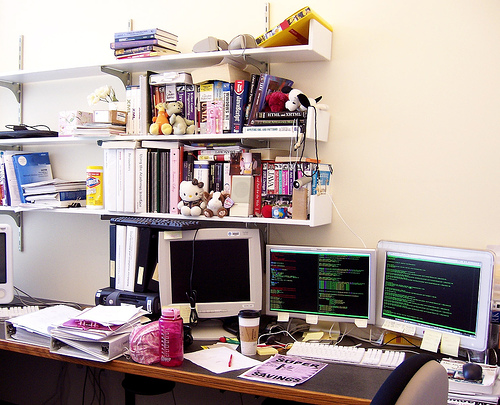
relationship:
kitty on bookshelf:
[175, 179, 207, 217] [0, 1, 333, 254]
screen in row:
[158, 229, 262, 319] [156, 228, 494, 352]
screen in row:
[264, 245, 378, 326] [156, 228, 494, 352]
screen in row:
[375, 240, 495, 351] [156, 228, 494, 352]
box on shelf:
[254, 7, 334, 47] [0, 5, 334, 85]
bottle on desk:
[158, 305, 182, 367] [0, 339, 496, 401]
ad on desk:
[238, 352, 328, 387] [3, 296, 494, 399]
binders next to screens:
[109, 224, 152, 293] [157, 229, 494, 355]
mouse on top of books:
[460, 363, 481, 383] [439, 358, 499, 399]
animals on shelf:
[150, 99, 197, 139] [0, 106, 330, 146]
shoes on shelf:
[0, 124, 56, 137] [0, 106, 330, 146]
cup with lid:
[238, 318, 260, 358] [236, 310, 258, 318]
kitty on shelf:
[175, 178, 208, 217] [0, 196, 334, 229]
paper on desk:
[237, 354, 329, 387] [3, 296, 494, 399]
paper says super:
[237, 354, 329, 387] [275, 358, 317, 369]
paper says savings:
[237, 354, 329, 387] [249, 370, 300, 384]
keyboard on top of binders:
[109, 215, 204, 232] [107, 223, 157, 294]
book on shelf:
[253, 6, 311, 47] [0, 19, 332, 79]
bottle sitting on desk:
[158, 305, 182, 367] [3, 296, 494, 399]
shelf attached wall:
[0, 196, 334, 229] [2, 0, 497, 402]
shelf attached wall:
[0, 106, 330, 146] [2, 0, 497, 402]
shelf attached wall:
[0, 19, 332, 79] [2, 0, 497, 402]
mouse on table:
[457, 356, 484, 383] [0, 296, 499, 404]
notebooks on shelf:
[99, 147, 149, 214] [6, 16, 335, 230]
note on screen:
[435, 327, 462, 357] [375, 240, 495, 351]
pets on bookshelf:
[142, 96, 236, 223] [0, 20, 333, 229]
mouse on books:
[460, 363, 481, 383] [441, 353, 499, 403]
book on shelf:
[237, 120, 298, 134] [99, 58, 333, 145]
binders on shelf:
[93, 138, 180, 214] [95, 140, 335, 234]